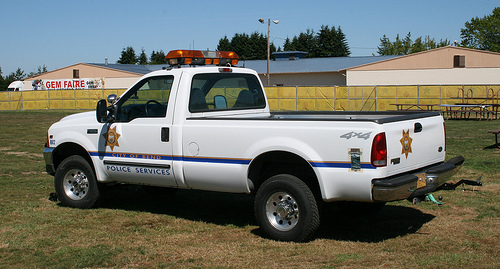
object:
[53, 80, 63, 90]
letter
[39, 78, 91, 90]
letter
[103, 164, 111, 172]
letter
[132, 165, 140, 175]
letter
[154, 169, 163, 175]
letter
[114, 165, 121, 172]
letter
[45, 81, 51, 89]
letter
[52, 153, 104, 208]
wheel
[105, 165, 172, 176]
letter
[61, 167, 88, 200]
rim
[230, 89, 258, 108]
seat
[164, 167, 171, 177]
letter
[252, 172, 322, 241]
wheel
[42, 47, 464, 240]
pick up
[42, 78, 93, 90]
banner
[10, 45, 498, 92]
building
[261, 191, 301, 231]
rim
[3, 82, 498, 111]
fence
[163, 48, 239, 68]
lights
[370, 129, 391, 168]
light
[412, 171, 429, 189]
license plate